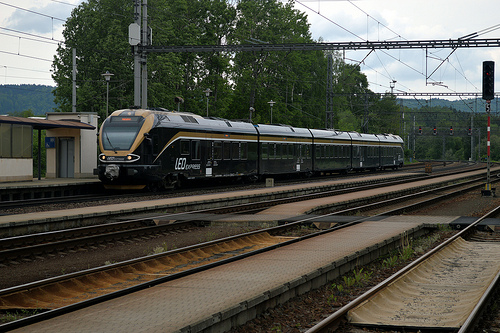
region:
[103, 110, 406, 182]
black and tan train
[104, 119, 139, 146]
glass windshield of train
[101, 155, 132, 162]
round headlights on train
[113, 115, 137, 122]
electronic destination sign on train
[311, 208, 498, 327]
wood and metal train tracks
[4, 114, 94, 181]
tan train station building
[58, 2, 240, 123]
tree with green leaves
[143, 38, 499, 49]
metal electrical tain pole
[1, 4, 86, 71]
black rubber electrical wires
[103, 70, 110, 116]
grey metal street lamp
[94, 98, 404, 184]
A black train with gold trim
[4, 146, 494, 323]
a couple of train tracks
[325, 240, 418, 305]
patches of green grass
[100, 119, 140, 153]
the front windsheild of a train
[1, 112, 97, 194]
a train station stop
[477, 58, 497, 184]
a train traffic light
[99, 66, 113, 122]
a lamp that is not on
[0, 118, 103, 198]
a train platform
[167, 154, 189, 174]
the word LED in white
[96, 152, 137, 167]
two headlights on a train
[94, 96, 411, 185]
black train on train tracks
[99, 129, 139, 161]
front window of black train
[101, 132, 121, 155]
windshield wiper on train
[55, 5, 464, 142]
stand of trees behind train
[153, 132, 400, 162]
white stripe on train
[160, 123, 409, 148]
gold stripe on train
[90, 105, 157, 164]
gold on front of train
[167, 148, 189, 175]
white writing on side of train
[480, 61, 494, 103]
black traffic light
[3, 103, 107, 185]
two buildings on train platform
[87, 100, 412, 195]
black train coming down the tracks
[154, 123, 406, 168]
two stripes running down train's side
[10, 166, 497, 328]
unused train tracks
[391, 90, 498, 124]
mountains in the distance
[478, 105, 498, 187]
red and white pole traffic light is attached to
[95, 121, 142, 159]
front window of train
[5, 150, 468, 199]
track train is on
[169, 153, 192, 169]
white lettering on side of train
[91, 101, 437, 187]
a black train on tracks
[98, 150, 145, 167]
the headlights on train are on.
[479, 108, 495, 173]
a red pole with white stripes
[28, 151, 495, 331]
several empty tracks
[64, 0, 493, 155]
A line of trees beside the train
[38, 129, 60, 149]
a blue and white sign on the building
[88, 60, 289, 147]
several light poles beside train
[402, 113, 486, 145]
red signal lights behind train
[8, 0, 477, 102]
wires in the air above train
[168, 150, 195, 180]
white letters spell LEO